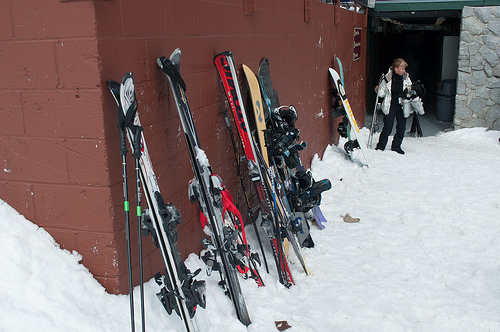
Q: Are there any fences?
A: No, there are no fences.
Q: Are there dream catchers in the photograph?
A: No, there are no dream catchers.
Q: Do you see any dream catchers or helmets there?
A: No, there are no dream catchers or helmets.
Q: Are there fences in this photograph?
A: No, there are no fences.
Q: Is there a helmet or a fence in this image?
A: No, there are no fences or helmets.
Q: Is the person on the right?
A: Yes, the person is on the right of the image.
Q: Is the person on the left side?
A: No, the person is on the right of the image.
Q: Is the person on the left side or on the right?
A: The person is on the right of the image.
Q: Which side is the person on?
A: The person is on the right of the image.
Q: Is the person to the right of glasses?
A: No, the person is to the right of the skis.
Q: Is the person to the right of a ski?
A: Yes, the person is to the right of a ski.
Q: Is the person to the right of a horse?
A: No, the person is to the right of a ski.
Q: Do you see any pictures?
A: No, there are no pictures.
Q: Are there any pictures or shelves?
A: No, there are no pictures or shelves.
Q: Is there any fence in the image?
A: No, there are no fences.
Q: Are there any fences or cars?
A: No, there are no fences or cars.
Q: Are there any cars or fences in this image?
A: No, there are no fences or cars.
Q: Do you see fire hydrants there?
A: No, there are no fire hydrants.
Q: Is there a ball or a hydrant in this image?
A: No, there are no fire hydrants or balls.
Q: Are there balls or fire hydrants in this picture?
A: No, there are no fire hydrants or balls.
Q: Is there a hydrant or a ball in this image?
A: No, there are no fire hydrants or balls.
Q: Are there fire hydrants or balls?
A: No, there are no fire hydrants or balls.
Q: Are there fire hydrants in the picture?
A: No, there are no fire hydrants.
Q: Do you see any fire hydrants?
A: No, there are no fire hydrants.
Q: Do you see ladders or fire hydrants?
A: No, there are no fire hydrants or ladders.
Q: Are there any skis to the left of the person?
A: Yes, there is a ski to the left of the person.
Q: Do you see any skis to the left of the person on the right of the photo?
A: Yes, there is a ski to the left of the person.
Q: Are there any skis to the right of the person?
A: No, the ski is to the left of the person.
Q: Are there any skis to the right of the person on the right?
A: No, the ski is to the left of the person.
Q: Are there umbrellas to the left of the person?
A: No, there is a ski to the left of the person.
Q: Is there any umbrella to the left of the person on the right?
A: No, there is a ski to the left of the person.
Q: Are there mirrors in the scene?
A: No, there are no mirrors.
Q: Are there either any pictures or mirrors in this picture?
A: No, there are no mirrors or pictures.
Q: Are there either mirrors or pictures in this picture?
A: No, there are no mirrors or pictures.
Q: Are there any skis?
A: Yes, there are skis.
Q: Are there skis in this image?
A: Yes, there are skis.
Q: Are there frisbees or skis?
A: Yes, there are skis.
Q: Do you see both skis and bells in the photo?
A: No, there are skis but no bells.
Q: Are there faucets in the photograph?
A: No, there are no faucets.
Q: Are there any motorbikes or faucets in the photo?
A: No, there are no faucets or motorbikes.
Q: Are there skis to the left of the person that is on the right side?
A: Yes, there are skis to the left of the person.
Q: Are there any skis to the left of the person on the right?
A: Yes, there are skis to the left of the person.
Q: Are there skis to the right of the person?
A: No, the skis are to the left of the person.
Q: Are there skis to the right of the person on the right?
A: No, the skis are to the left of the person.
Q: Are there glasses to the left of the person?
A: No, there are skis to the left of the person.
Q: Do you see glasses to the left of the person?
A: No, there are skis to the left of the person.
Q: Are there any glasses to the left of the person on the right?
A: No, there are skis to the left of the person.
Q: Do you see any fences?
A: No, there are no fences.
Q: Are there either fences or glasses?
A: No, there are no fences or glasses.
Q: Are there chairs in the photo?
A: No, there are no chairs.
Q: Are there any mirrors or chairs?
A: No, there are no chairs or mirrors.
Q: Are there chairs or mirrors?
A: No, there are no chairs or mirrors.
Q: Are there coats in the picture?
A: Yes, there is a coat.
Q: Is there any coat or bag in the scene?
A: Yes, there is a coat.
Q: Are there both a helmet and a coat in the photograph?
A: No, there is a coat but no helmets.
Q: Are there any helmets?
A: No, there are no helmets.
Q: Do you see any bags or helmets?
A: No, there are no helmets or bags.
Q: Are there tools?
A: No, there are no tools.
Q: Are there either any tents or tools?
A: No, there are no tools or tents.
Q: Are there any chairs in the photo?
A: No, there are no chairs.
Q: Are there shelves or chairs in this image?
A: No, there are no chairs or shelves.